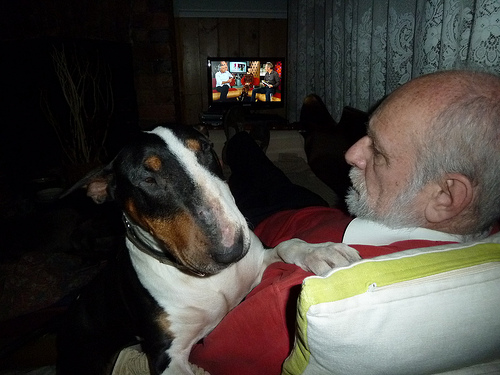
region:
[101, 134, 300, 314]
the dog is black and white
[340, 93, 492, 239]
the guy is bald headed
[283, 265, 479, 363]
the pillow is grren and white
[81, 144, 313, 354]
the dog has a collar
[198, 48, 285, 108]
the tv is on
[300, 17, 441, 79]
the curtain is decorated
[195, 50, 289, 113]
the tv is flat screen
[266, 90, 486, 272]
the man is old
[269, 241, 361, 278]
the paws are on the man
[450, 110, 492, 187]
the hair is white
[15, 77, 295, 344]
the dog is black white and brown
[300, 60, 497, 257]
man is looking at the dog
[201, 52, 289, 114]
the tv screen is on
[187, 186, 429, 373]
man's shirt is red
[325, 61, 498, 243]
man's hair is gray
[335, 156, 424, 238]
man has a beard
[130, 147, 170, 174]
brown spot on dog's face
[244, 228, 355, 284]
dog's paw is on man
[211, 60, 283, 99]
people talking on tv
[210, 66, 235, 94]
person's shirt is white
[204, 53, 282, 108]
A turned on television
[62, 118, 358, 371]
A cuddling dog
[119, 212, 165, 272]
A dog's collar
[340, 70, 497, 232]
A man's face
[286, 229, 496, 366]
A white and green pillow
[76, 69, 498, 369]
A man cuddling with his dog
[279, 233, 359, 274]
A dog's front paw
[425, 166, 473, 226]
A man's ear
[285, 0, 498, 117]
A lace curtain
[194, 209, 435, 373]
A red shirt with a white collar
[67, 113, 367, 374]
black, tan, and white dog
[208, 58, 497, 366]
man wearing red shirt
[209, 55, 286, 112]
black flatscreen tv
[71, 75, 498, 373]
man and dog sitting together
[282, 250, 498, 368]
white and green pillow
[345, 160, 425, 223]
white beard and moustache of man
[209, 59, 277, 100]
show playing on television screen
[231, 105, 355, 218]
dark pants man is wearing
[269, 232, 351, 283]
white paw on man's shoulder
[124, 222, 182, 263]
black collar of the dog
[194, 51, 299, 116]
Television in background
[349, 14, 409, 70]
Blue and brown curtains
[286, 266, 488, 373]
White and green striped pillow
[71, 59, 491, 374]
Dog with paw on man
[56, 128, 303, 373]
Black white and brown dog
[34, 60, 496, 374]
Man sitting with dog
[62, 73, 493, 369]
Man sitting on couch with dog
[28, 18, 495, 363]
Man sitting on couch with dog watching TV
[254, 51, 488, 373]
Man wearing white sweater trimmed in white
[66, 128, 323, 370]
Dog looking into the camera